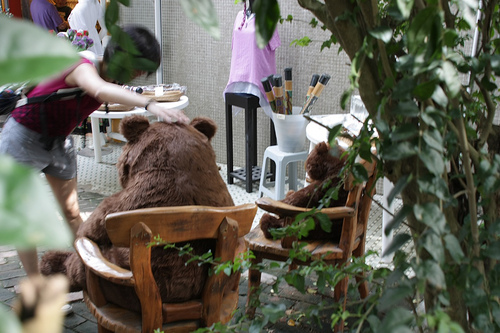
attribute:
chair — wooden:
[246, 153, 372, 330]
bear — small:
[259, 135, 356, 249]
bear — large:
[38, 111, 246, 329]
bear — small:
[275, 126, 361, 273]